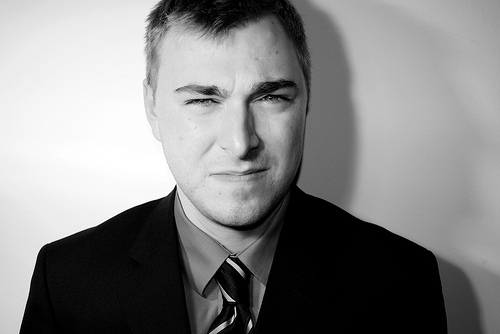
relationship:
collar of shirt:
[176, 222, 227, 301] [181, 225, 275, 326]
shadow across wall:
[316, 22, 393, 183] [30, 32, 111, 133]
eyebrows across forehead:
[173, 82, 296, 93] [186, 43, 279, 67]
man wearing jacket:
[30, 5, 464, 330] [19, 187, 450, 333]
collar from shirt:
[176, 222, 227, 301] [181, 225, 275, 326]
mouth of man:
[209, 167, 271, 178] [30, 5, 464, 330]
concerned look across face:
[165, 65, 302, 193] [155, 30, 315, 229]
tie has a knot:
[210, 253, 254, 332] [213, 256, 254, 306]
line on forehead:
[221, 69, 242, 90] [186, 43, 279, 67]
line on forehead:
[241, 52, 270, 81] [186, 43, 279, 67]